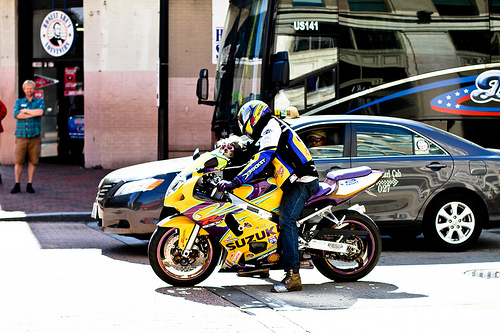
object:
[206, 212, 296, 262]
suzuki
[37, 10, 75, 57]
sign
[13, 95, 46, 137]
green shirt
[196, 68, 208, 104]
mirror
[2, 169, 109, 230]
sidewalk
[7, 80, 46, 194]
man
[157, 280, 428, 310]
motorbike's shadow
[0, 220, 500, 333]
road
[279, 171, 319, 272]
jeans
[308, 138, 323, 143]
sun glasses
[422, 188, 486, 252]
tire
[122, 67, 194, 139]
wall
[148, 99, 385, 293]
bicycle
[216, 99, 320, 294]
man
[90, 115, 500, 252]
car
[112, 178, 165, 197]
headlight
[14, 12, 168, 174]
shop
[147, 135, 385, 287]
bike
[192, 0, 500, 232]
bus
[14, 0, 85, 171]
door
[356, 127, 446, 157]
window